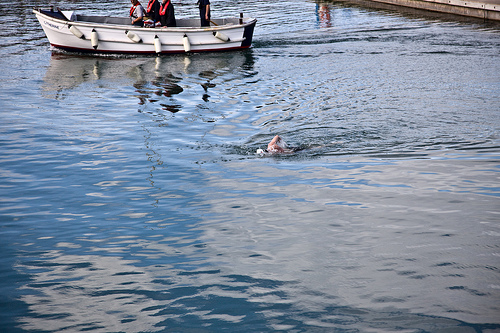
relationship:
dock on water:
[347, 0, 500, 24] [1, 2, 499, 331]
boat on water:
[29, 7, 259, 54] [1, 2, 499, 331]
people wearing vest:
[129, 0, 211, 29] [135, 1, 182, 26]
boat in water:
[29, 7, 259, 54] [1, 2, 499, 331]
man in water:
[250, 131, 315, 168] [1, 2, 499, 331]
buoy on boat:
[152, 35, 162, 58] [31, 9, 256, 61]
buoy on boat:
[65, 21, 87, 39] [31, 9, 256, 61]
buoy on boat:
[90, 28, 100, 55] [31, 9, 256, 61]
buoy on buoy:
[125, 28, 144, 46] [152, 35, 162, 58]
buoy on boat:
[178, 30, 191, 60] [31, 9, 256, 61]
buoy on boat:
[210, 29, 231, 44] [31, 9, 256, 61]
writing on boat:
[41, 20, 59, 30] [29, 7, 259, 54]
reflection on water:
[44, 48, 255, 214] [1, 2, 499, 331]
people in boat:
[129, 0, 211, 29] [29, 8, 339, 78]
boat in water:
[29, 7, 259, 54] [24, 49, 486, 331]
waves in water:
[43, 188, 490, 321] [1, 2, 499, 331]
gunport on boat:
[211, 29, 231, 41] [29, 7, 259, 54]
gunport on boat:
[178, 32, 190, 52] [29, 7, 259, 54]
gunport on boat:
[153, 33, 161, 53] [29, 7, 259, 54]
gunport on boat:
[125, 30, 141, 45] [29, 7, 259, 54]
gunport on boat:
[86, 27, 98, 50] [29, 7, 259, 54]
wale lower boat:
[32, 47, 196, 57] [29, 7, 259, 54]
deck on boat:
[72, 14, 246, 27] [29, 7, 259, 54]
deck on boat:
[38, 9, 238, 29] [29, 7, 259, 54]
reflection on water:
[311, 0, 336, 30] [1, 2, 499, 331]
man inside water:
[256, 134, 345, 157] [192, 202, 369, 301]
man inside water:
[256, 134, 345, 157] [1, 2, 499, 331]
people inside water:
[129, 0, 211, 29] [1, 2, 499, 331]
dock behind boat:
[347, 0, 499, 20] [29, 8, 256, 50]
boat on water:
[11, 6, 275, 51] [1, 2, 499, 331]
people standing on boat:
[129, 0, 211, 29] [29, 5, 258, 57]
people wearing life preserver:
[135, 0, 187, 42] [156, 4, 174, 24]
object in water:
[256, 124, 292, 155] [1, 2, 499, 331]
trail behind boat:
[247, 27, 451, 44] [29, 8, 256, 50]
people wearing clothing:
[129, 0, 211, 29] [143, 8, 178, 27]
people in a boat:
[129, 0, 211, 29] [29, 7, 259, 54]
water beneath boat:
[1, 2, 499, 331] [31, 9, 256, 61]